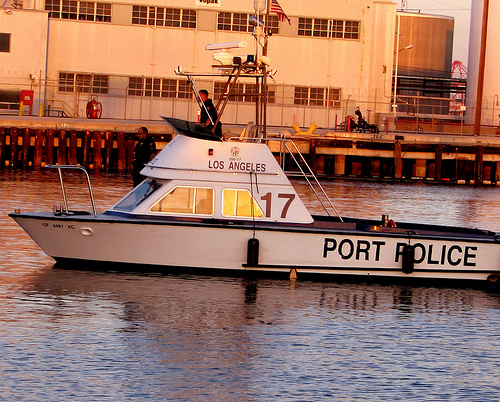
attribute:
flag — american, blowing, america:
[269, 0, 292, 25]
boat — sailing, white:
[6, 0, 499, 294]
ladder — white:
[264, 131, 347, 223]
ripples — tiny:
[320, 369, 400, 390]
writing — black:
[321, 236, 479, 267]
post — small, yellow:
[17, 100, 25, 117]